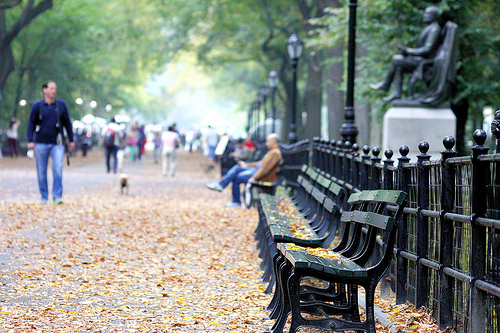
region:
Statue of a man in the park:
[370, 5, 459, 151]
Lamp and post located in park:
[286, 32, 303, 139]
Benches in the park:
[248, 163, 405, 328]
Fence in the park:
[282, 145, 497, 330]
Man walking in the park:
[22, 81, 71, 204]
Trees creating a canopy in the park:
[3, 0, 498, 150]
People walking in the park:
[70, 123, 230, 178]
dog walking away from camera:
[115, 170, 130, 195]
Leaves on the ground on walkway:
[5, 200, 266, 330]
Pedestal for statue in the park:
[382, 108, 455, 160]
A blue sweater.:
[24, 97, 76, 142]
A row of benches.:
[242, 162, 407, 332]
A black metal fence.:
[252, 107, 499, 332]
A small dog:
[119, 175, 129, 193]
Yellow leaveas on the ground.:
[1, 143, 271, 331]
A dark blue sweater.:
[26, 97, 73, 144]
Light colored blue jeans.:
[32, 142, 65, 198]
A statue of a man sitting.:
[369, 6, 459, 106]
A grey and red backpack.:
[101, 129, 115, 149]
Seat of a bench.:
[275, 240, 368, 277]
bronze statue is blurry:
[378, 5, 464, 107]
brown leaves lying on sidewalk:
[76, 223, 194, 294]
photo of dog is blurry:
[114, 173, 131, 193]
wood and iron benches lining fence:
[266, 167, 391, 330]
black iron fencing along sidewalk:
[420, 136, 494, 321]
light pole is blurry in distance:
[280, 33, 305, 140]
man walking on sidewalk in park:
[30, 77, 76, 203]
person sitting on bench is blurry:
[217, 133, 291, 198]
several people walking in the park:
[100, 118, 207, 168]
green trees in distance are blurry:
[49, 23, 121, 71]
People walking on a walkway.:
[5, 67, 287, 202]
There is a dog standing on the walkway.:
[110, 170, 135, 195]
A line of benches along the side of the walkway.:
[255, 160, 390, 325]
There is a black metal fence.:
[240, 127, 495, 322]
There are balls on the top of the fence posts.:
[310, 135, 490, 170]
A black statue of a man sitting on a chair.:
[365, 5, 455, 105]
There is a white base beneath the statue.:
[380, 105, 455, 160]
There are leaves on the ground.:
[10, 170, 255, 330]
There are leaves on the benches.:
[261, 175, 341, 275]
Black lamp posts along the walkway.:
[245, 30, 371, 138]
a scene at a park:
[18, 20, 488, 288]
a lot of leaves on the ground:
[14, 190, 264, 318]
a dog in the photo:
[115, 173, 152, 202]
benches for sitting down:
[245, 173, 394, 305]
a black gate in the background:
[315, 132, 490, 306]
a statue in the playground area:
[357, 1, 467, 121]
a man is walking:
[25, 76, 82, 220]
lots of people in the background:
[93, 114, 233, 166]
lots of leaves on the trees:
[53, 8, 253, 85]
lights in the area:
[227, 22, 306, 131]